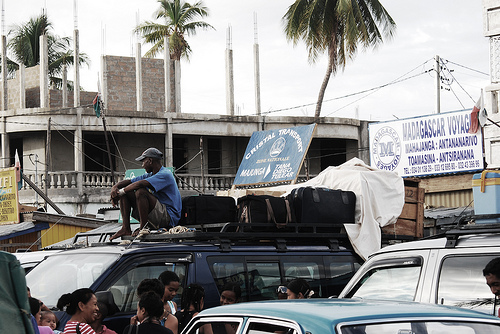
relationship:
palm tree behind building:
[286, 2, 394, 120] [2, 36, 370, 189]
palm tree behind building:
[134, 1, 211, 115] [2, 36, 370, 189]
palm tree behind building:
[1, 10, 86, 103] [2, 36, 370, 189]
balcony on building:
[3, 167, 318, 195] [2, 36, 370, 189]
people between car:
[131, 293, 175, 333] [173, 293, 495, 333]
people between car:
[60, 286, 98, 333] [173, 293, 495, 333]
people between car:
[174, 283, 213, 332] [173, 293, 495, 333]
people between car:
[159, 270, 179, 313] [173, 293, 495, 333]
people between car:
[283, 278, 317, 300] [173, 293, 495, 333]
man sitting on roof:
[112, 148, 182, 242] [64, 233, 353, 250]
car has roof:
[12, 230, 367, 334] [64, 233, 353, 250]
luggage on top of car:
[167, 188, 358, 238] [12, 230, 367, 334]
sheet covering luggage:
[220, 157, 403, 266] [167, 188, 358, 238]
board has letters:
[367, 110, 486, 182] [397, 116, 480, 174]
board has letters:
[230, 124, 318, 189] [237, 130, 303, 179]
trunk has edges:
[471, 167, 499, 218] [472, 169, 500, 190]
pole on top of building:
[254, 47, 262, 114] [2, 36, 370, 189]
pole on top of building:
[226, 49, 236, 119] [2, 36, 370, 189]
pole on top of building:
[165, 33, 173, 112] [2, 36, 370, 189]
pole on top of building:
[134, 39, 145, 115] [2, 36, 370, 189]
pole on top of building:
[73, 29, 83, 110] [2, 36, 370, 189]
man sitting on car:
[112, 148, 182, 242] [12, 230, 367, 334]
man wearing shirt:
[112, 148, 182, 242] [132, 163, 183, 231]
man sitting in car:
[112, 148, 182, 242] [12, 230, 367, 334]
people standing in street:
[60, 286, 98, 333] [5, 236, 414, 332]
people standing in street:
[131, 293, 175, 333] [5, 236, 414, 332]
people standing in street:
[159, 270, 179, 313] [5, 236, 414, 332]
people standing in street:
[174, 283, 213, 332] [5, 236, 414, 332]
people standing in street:
[283, 278, 317, 300] [5, 236, 414, 332]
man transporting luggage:
[112, 148, 182, 242] [167, 188, 358, 238]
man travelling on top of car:
[112, 148, 182, 242] [12, 230, 367, 334]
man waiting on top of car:
[112, 148, 182, 242] [12, 230, 367, 334]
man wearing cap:
[112, 148, 182, 242] [133, 148, 164, 164]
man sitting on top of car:
[112, 148, 182, 242] [12, 230, 367, 334]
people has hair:
[60, 286, 98, 333] [55, 286, 96, 317]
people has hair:
[131, 293, 175, 333] [140, 291, 163, 315]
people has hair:
[283, 278, 317, 300] [286, 277, 313, 299]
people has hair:
[174, 283, 213, 332] [183, 282, 204, 323]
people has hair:
[159, 270, 179, 313] [158, 271, 179, 286]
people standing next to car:
[60, 286, 98, 333] [12, 230, 367, 334]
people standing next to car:
[131, 293, 175, 333] [12, 230, 367, 334]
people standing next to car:
[159, 270, 179, 313] [12, 230, 367, 334]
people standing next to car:
[174, 283, 213, 332] [12, 230, 367, 334]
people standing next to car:
[283, 278, 317, 300] [12, 230, 367, 334]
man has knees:
[112, 148, 182, 242] [118, 179, 154, 208]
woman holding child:
[30, 297, 51, 332] [40, 311, 59, 333]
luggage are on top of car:
[167, 188, 358, 238] [12, 230, 367, 334]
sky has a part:
[1, 1, 488, 121] [389, 18, 463, 76]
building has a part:
[2, 36, 370, 189] [79, 104, 109, 140]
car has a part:
[340, 228, 499, 312] [409, 246, 442, 312]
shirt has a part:
[132, 163, 183, 231] [165, 182, 174, 203]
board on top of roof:
[230, 124, 318, 189] [64, 233, 353, 250]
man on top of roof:
[112, 148, 182, 242] [64, 233, 353, 250]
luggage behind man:
[167, 188, 358, 238] [112, 148, 182, 242]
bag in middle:
[239, 196, 298, 226] [234, 156, 306, 250]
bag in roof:
[239, 196, 298, 226] [64, 233, 353, 250]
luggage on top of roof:
[167, 188, 358, 238] [64, 233, 353, 250]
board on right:
[367, 110, 486, 182] [357, 75, 495, 208]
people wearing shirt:
[60, 286, 98, 333] [65, 319, 95, 333]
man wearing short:
[112, 148, 182, 242] [144, 196, 170, 230]